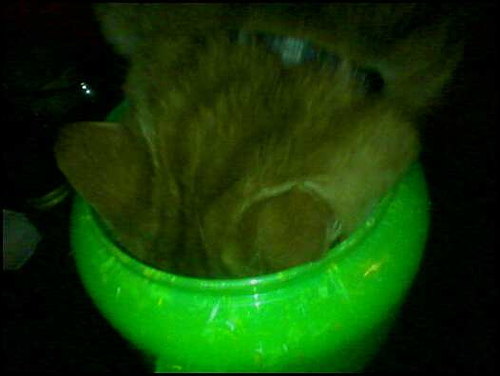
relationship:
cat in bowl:
[53, 0, 483, 280] [64, 128, 429, 368]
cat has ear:
[53, 0, 483, 280] [52, 119, 170, 251]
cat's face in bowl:
[85, 84, 417, 252] [65, 204, 472, 353]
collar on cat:
[217, 21, 388, 101] [53, 0, 483, 280]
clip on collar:
[276, 40, 373, 89] [236, 27, 384, 97]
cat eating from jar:
[53, 0, 483, 280] [73, 160, 433, 368]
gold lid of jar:
[35, 182, 70, 209] [43, 205, 70, 232]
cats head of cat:
[52, 101, 420, 278] [85, 40, 390, 234]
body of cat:
[99, 2, 497, 112] [53, 0, 483, 280]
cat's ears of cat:
[52, 121, 330, 274] [56, 1, 498, 255]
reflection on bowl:
[249, 271, 269, 305] [58, 86, 442, 374]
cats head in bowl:
[52, 101, 420, 278] [67, 76, 441, 360]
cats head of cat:
[52, 101, 420, 278] [53, 0, 483, 280]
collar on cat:
[202, 28, 387, 101] [90, 12, 416, 222]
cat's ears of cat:
[52, 121, 330, 274] [33, 9, 498, 284]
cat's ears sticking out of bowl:
[44, 110, 336, 265] [72, 142, 429, 374]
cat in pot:
[53, 0, 483, 280] [62, 160, 435, 374]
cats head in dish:
[48, 56, 408, 281] [42, 97, 447, 367]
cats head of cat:
[52, 101, 420, 278] [49, 51, 426, 268]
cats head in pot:
[52, 101, 420, 278] [62, 160, 435, 374]